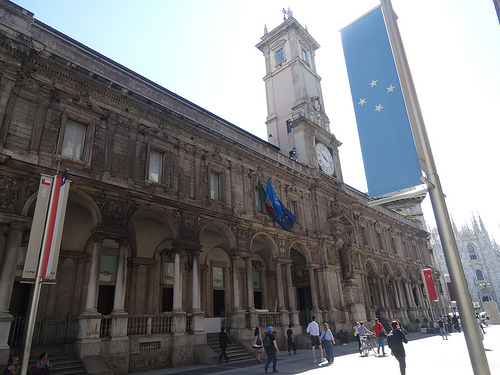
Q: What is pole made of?
A: Metal.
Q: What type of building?
A: Historical.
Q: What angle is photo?
A: Slanted.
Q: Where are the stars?
A: On flag.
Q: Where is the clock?
A: On tower.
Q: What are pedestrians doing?
A: Walking.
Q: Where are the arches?
A: On building.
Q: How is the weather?
A: Sunny.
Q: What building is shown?
A: Stone.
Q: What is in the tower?
A: Clock.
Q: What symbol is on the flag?
A: Stars.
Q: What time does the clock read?
A: 3:50.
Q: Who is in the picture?
A: Tourists.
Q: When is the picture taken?
A: Daytime.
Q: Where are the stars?
A: On blue flag.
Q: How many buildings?
A: Two.